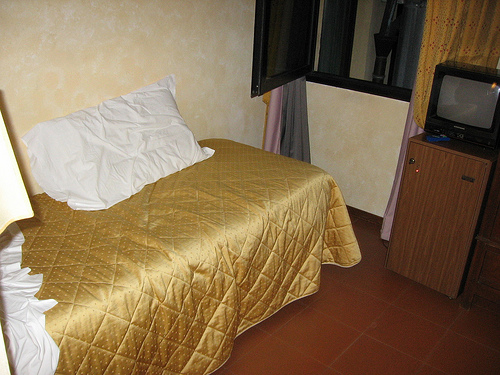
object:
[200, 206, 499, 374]
floor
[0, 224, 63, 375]
sheets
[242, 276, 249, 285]
patch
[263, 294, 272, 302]
patch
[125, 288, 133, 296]
patch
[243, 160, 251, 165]
patch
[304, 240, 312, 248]
patch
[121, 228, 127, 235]
patch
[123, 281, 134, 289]
patch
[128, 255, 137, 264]
patch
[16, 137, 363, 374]
bedspread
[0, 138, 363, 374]
bed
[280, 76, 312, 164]
curtain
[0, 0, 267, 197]
wall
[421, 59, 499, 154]
television